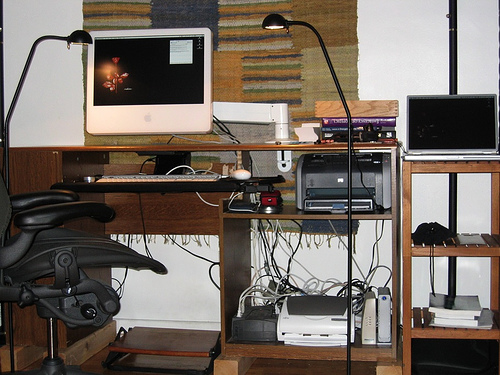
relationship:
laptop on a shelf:
[403, 91, 499, 169] [399, 151, 497, 340]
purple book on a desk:
[323, 116, 401, 125] [8, 140, 403, 374]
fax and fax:
[295, 153, 395, 214] [295, 152, 392, 214]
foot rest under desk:
[118, 312, 223, 359] [34, 130, 396, 347]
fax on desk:
[295, 152, 392, 214] [1, 139, 402, 375]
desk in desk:
[1, 139, 402, 375] [32, 117, 426, 367]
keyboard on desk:
[97, 173, 220, 181] [8, 140, 403, 374]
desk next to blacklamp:
[1, 139, 498, 373] [261, 13, 353, 375]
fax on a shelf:
[295, 152, 392, 214] [135, 112, 452, 312]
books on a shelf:
[423, 286, 491, 328] [272, 128, 355, 153]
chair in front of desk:
[3, 167, 160, 351] [8, 140, 403, 374]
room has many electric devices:
[1, 3, 481, 373] [88, 25, 403, 296]